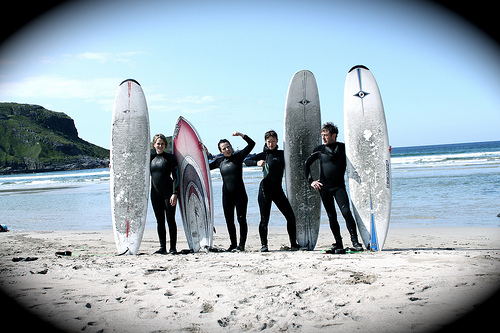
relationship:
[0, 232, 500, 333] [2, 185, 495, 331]
san pit on beach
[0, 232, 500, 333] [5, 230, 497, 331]
san pit in beach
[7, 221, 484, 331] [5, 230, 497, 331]
san pit on beach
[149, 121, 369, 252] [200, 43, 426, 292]
people holds surfboards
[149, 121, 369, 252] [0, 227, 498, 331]
people on sand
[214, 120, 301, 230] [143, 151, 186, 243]
person wears wet suit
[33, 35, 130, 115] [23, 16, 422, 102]
clouds in sky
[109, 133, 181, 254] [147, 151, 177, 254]
people in wetsuit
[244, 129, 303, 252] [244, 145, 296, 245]
person in wet suit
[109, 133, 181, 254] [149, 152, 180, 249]
people in wet suit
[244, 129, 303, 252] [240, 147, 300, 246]
person wearing wet suit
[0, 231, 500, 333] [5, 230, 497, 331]
sand pit on beach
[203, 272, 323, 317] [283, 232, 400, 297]
sand on beach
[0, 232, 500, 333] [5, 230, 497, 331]
san pit on beach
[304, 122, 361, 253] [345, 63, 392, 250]
person holding surfboard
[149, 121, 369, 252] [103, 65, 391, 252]
people holding surf boards